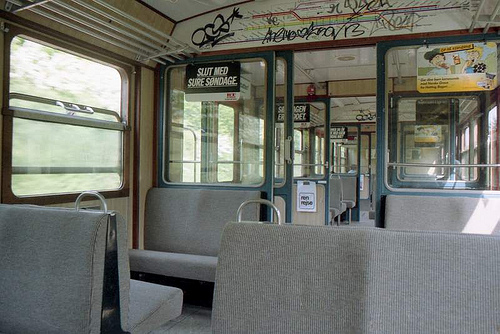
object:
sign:
[184, 61, 241, 102]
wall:
[158, 0, 500, 63]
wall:
[162, 0, 500, 55]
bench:
[129, 187, 262, 284]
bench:
[0, 202, 109, 334]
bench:
[212, 222, 500, 334]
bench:
[384, 194, 500, 236]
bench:
[108, 211, 184, 333]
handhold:
[235, 198, 281, 224]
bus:
[0, 0, 500, 334]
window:
[9, 36, 122, 198]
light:
[460, 199, 500, 235]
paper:
[183, 62, 240, 102]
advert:
[416, 41, 498, 93]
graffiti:
[190, 6, 243, 47]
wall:
[161, 0, 500, 59]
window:
[11, 112, 124, 197]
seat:
[209, 199, 500, 334]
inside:
[273, 45, 376, 227]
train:
[0, 0, 498, 333]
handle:
[235, 198, 282, 225]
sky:
[11, 35, 121, 122]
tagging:
[369, 29, 376, 36]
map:
[213, 0, 471, 47]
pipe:
[388, 162, 490, 167]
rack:
[93, 0, 203, 56]